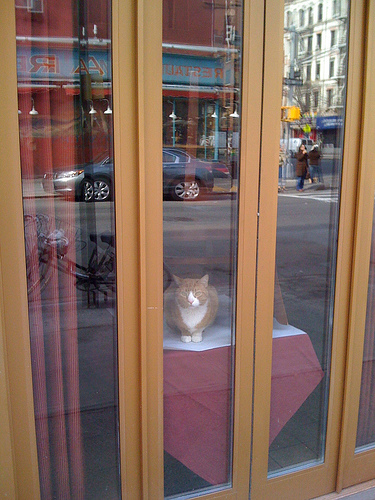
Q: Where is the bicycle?
A: On the sidewalk.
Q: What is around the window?
A: Frame.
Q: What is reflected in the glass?
A: Car.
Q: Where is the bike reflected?
A: Glass.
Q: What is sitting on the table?
A: Cat.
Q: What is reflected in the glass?
A: Bike.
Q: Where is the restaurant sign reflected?
A: Above the car reflection.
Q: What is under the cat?
A: Table cloth.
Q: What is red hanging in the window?
A: Curtains.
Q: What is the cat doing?
A: Sitting on table.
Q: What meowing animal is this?
A: Cat.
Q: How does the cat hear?
A: Ears.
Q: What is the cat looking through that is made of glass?
A: Window.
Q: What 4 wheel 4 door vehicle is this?
A: Car.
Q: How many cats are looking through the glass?
A: One.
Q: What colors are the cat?
A: White and orange.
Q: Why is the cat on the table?
A: To see better.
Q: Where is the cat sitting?
A: On a table.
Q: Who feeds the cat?
A: His owner.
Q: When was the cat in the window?
A: Daytime.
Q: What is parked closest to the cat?
A: Bike.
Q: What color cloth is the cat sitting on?
A: White.